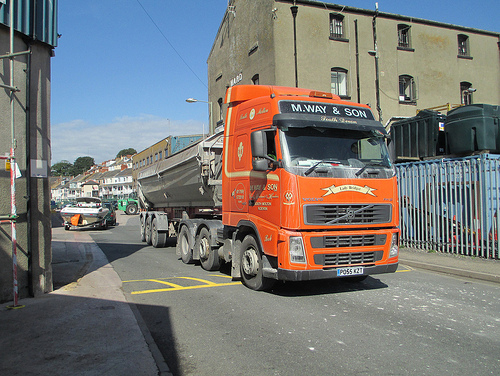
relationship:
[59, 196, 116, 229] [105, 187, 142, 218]
boat on towing trailer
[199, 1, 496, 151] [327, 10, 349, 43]
building has window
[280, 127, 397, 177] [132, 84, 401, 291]
windshield on large truck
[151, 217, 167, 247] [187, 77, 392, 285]
tire on truck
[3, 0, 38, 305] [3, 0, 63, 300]
scaffolding on side building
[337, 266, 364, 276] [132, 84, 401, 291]
license plate on front large truck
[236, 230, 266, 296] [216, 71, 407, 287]
tire on truck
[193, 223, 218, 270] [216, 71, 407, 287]
tire on truck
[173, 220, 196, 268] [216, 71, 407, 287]
tire on truck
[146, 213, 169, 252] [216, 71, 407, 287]
tire on truck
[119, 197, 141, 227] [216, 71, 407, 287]
tire on truck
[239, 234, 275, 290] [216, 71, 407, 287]
tire on truck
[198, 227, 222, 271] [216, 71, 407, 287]
tire on truck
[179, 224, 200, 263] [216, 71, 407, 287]
tire on truck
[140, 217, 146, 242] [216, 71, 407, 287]
tires on truck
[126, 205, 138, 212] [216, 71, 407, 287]
wheel on truck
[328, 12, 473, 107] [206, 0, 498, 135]
windows on side building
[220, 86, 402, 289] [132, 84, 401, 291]
cab of large truck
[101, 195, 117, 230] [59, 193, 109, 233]
car towing boat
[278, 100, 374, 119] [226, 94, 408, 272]
sign on truck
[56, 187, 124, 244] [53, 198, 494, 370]
boat towed on street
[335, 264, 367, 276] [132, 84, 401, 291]
license plate on large truck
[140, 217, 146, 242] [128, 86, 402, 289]
tires on truck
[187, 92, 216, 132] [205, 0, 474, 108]
street light near building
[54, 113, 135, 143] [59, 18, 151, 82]
clouds in sky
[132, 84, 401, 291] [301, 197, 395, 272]
large truck has vents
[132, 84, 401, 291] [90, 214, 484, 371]
large truck on street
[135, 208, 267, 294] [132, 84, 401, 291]
tires on large truck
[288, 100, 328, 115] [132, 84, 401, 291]
m.way written on large truck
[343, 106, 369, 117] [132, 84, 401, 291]
son written on large truck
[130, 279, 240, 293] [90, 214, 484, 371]
line painted on street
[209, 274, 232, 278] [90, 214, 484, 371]
line painted on street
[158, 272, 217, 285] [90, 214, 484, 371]
line painted on street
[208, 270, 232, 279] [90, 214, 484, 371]
line painted on street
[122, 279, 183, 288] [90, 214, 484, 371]
line painted on street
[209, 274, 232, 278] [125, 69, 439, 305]
line painted next to truck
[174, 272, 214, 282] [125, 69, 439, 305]
line painted next to truck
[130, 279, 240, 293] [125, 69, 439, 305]
line painted next to truck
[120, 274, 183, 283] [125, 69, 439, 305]
line painted next to truck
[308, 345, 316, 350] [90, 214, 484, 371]
spot soiling street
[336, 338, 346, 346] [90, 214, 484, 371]
spot soiling street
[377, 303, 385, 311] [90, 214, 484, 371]
spot soiling street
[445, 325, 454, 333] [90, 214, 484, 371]
spot soiling street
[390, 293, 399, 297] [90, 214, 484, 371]
spot soiling street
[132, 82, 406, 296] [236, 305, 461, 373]
large truck on street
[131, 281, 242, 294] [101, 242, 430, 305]
line on speedbump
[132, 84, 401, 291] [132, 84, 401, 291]
large truck with large truck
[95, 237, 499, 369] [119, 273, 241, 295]
street has lines